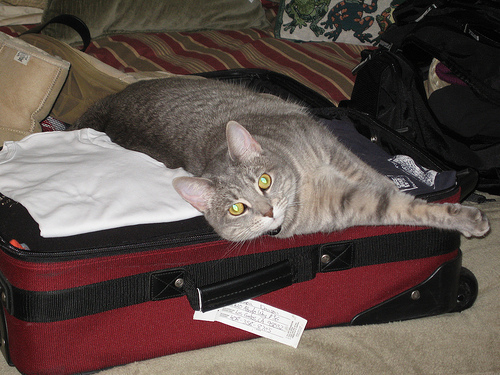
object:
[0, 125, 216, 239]
clothes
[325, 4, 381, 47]
frog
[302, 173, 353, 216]
fur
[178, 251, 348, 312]
handle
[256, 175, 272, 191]
eyes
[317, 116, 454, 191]
clothing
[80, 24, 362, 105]
sheet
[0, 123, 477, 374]
bag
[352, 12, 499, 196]
black bag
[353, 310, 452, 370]
beige carpet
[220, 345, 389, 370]
beige blanket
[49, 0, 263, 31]
dark grey pillow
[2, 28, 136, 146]
pair of boots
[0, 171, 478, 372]
black suit case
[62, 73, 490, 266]
adult cat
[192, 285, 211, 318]
string on name tag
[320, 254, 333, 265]
small screw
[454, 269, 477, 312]
black wheel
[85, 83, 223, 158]
cat with gray fur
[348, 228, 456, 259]
black trim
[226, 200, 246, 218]
cat with green eyes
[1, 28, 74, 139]
light brown boot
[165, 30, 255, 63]
green striped fabric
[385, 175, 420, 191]
white design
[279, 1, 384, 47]
frog print pillow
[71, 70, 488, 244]
cat is in colour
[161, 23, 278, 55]
sheet is red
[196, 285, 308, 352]
bag has a tag